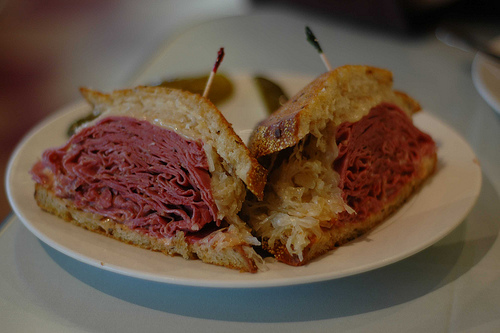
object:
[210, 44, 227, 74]
plastic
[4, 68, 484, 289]
plate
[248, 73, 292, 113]
pickle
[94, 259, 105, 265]
speck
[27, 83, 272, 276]
sandwhich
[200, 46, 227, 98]
tooth pick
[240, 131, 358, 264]
saurkraut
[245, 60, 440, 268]
sandwhich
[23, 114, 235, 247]
ham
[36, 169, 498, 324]
shadow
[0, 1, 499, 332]
table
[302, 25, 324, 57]
wrapper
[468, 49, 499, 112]
utensil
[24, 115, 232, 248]
corned beef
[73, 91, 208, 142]
swiss cheese